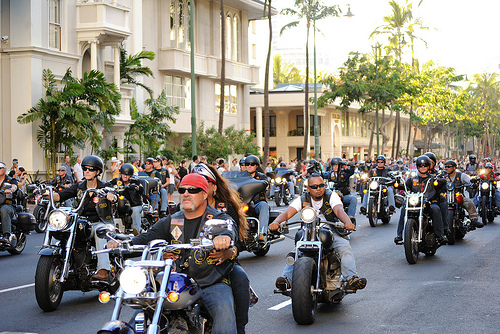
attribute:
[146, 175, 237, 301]
person — man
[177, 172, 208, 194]
bandana — red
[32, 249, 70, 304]
wheel — black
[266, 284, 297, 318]
line — white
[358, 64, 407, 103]
leaves — green